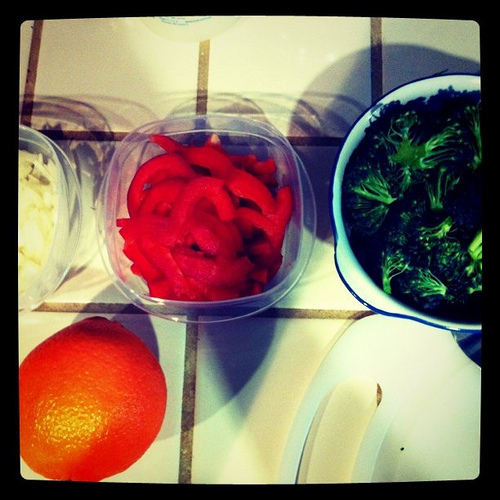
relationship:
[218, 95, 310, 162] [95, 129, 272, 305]
bowl has food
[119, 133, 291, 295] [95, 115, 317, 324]
peppers are in bowl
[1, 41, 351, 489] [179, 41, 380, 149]
lines around tile